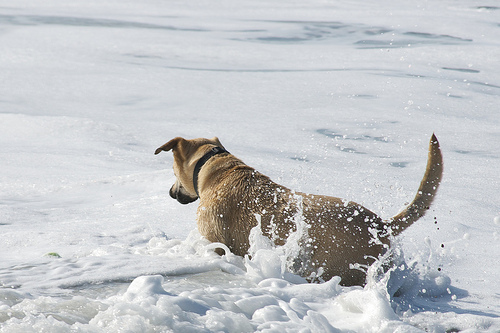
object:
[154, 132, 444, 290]
dog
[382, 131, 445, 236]
brown tail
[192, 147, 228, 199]
black collar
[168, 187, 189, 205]
black snout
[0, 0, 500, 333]
snow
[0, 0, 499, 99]
tracks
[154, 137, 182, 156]
ear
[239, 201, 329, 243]
wet fur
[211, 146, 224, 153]
buckle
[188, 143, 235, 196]
dog neck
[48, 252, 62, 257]
tennis ball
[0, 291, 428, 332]
water